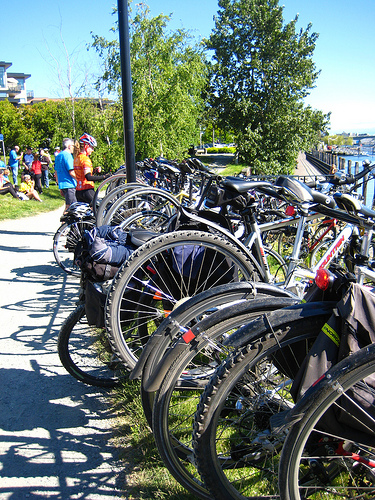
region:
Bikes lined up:
[76, 169, 291, 384]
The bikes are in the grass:
[104, 388, 266, 497]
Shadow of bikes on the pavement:
[1, 324, 121, 497]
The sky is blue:
[2, 1, 374, 122]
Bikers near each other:
[5, 136, 119, 209]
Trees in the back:
[181, 5, 332, 155]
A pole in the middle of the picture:
[79, 9, 196, 228]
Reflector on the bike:
[271, 218, 360, 311]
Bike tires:
[100, 274, 331, 429]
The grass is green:
[116, 382, 298, 498]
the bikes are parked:
[72, 133, 351, 474]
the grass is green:
[120, 396, 167, 486]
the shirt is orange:
[69, 148, 122, 228]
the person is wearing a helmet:
[65, 124, 127, 194]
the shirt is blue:
[56, 148, 76, 195]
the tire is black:
[118, 240, 292, 379]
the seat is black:
[220, 169, 293, 215]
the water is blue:
[348, 155, 372, 173]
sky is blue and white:
[319, 31, 373, 116]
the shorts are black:
[68, 185, 121, 217]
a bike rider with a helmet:
[75, 131, 112, 206]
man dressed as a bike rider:
[74, 131, 113, 205]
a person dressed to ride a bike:
[74, 132, 112, 211]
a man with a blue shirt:
[55, 138, 76, 225]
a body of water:
[333, 155, 373, 210]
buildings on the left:
[0, 59, 45, 108]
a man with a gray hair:
[54, 136, 77, 219]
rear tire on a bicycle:
[102, 232, 265, 392]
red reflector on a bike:
[180, 327, 195, 345]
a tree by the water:
[202, 1, 330, 178]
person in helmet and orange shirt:
[72, 133, 110, 205]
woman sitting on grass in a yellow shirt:
[15, 173, 41, 201]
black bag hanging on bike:
[287, 278, 374, 441]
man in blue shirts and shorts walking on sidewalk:
[54, 137, 76, 228]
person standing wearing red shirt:
[30, 152, 42, 192]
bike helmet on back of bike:
[67, 201, 93, 218]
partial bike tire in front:
[269, 342, 374, 496]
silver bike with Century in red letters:
[222, 174, 372, 292]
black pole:
[118, 0, 140, 206]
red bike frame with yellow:
[304, 217, 336, 249]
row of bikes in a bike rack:
[30, 75, 372, 477]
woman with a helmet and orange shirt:
[60, 118, 128, 220]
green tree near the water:
[192, 20, 371, 203]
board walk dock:
[258, 86, 374, 223]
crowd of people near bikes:
[2, 84, 126, 255]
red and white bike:
[105, 142, 371, 458]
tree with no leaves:
[31, 17, 97, 121]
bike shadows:
[0, 137, 131, 493]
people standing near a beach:
[19, 49, 371, 427]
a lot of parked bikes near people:
[31, 101, 354, 472]